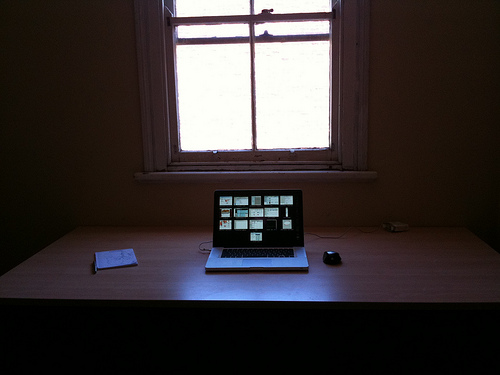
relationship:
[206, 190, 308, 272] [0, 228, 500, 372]
laptop on desk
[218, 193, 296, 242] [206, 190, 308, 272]
monitor on laptop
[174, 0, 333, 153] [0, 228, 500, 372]
window above desk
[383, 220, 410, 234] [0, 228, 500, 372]
object on desk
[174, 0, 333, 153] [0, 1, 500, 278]
window on wall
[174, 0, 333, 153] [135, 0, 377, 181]
window has sill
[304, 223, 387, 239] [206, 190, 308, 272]
cable connected to laptop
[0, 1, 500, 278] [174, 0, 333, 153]
wall by window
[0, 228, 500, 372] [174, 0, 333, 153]
desk under window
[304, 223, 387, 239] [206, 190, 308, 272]
cable touching laptop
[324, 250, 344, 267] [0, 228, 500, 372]
mouse on desk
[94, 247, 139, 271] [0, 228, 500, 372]
paper on desk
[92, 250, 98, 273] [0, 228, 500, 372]
pencil on desk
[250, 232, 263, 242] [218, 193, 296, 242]
picture on monitor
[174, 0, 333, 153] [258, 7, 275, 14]
window has latch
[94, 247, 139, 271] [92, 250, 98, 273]
paper by pencil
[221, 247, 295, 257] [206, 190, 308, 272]
keyboard on laptop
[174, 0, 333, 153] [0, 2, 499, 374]
window on room